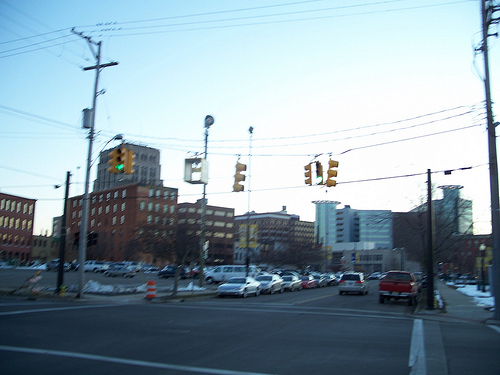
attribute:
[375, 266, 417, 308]
truck — red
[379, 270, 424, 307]
truck — red, the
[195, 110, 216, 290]
light pole — street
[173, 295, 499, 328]
lines — white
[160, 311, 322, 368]
road — the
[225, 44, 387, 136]
clouds — white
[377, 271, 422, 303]
red truck — the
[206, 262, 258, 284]
van — the, large, white, passenger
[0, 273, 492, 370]
street — the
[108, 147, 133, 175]
light — green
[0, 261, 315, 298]
parking lot — a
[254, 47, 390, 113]
sky — blue, cloudy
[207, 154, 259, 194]
signal — light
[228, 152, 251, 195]
traffic signal — light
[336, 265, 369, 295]
car — a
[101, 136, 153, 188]
traffic light — green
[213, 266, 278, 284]
van — the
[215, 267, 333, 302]
cars — line, parked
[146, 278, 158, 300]
barrel — green, white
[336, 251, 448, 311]
truck — red, the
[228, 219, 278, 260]
sign — yellow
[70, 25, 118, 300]
pole — utility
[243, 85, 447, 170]
clouds — white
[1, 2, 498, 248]
sky — blue, cloudy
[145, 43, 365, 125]
sky — the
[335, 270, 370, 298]
car — silver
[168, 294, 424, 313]
line — white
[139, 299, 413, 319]
line — white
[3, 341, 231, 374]
line — white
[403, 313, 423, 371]
line — white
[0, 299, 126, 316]
line — white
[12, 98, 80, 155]
clouds — white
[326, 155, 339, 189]
signal — light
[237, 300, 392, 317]
line — white